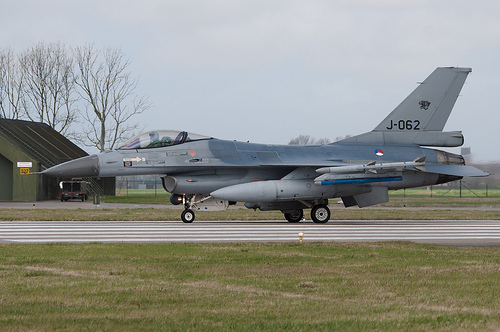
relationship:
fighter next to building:
[28, 66, 491, 221] [7, 130, 43, 198]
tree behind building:
[3, 62, 25, 113] [7, 130, 43, 198]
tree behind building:
[37, 66, 68, 122] [7, 130, 43, 198]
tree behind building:
[85, 84, 110, 139] [7, 130, 43, 198]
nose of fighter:
[35, 161, 97, 174] [28, 66, 491, 221]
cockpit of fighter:
[126, 126, 197, 148] [28, 66, 491, 221]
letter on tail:
[389, 119, 395, 137] [375, 63, 452, 142]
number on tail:
[401, 120, 423, 132] [375, 63, 452, 142]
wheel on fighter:
[312, 209, 335, 228] [28, 66, 491, 221]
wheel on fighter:
[179, 209, 199, 224] [28, 66, 491, 221]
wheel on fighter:
[290, 210, 302, 220] [28, 66, 491, 221]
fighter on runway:
[28, 66, 491, 221] [48, 225, 496, 238]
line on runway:
[62, 227, 71, 229] [48, 225, 496, 238]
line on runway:
[124, 232, 139, 237] [48, 225, 496, 238]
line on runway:
[163, 228, 169, 229] [48, 225, 496, 238]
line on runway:
[104, 219, 108, 222] [48, 225, 496, 238]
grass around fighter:
[51, 211, 173, 219] [28, 66, 491, 221]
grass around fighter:
[383, 209, 493, 221] [28, 66, 491, 221]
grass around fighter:
[23, 252, 499, 314] [28, 66, 491, 221]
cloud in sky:
[355, 27, 433, 56] [146, 9, 443, 64]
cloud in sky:
[94, 11, 153, 33] [146, 9, 443, 64]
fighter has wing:
[28, 66, 491, 221] [433, 163, 488, 176]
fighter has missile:
[28, 66, 491, 221] [326, 166, 417, 170]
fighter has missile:
[28, 66, 491, 221] [236, 185, 321, 198]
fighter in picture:
[28, 66, 491, 221] [1, 0, 498, 327]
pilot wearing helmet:
[145, 126, 159, 145] [147, 129, 156, 142]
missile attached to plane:
[315, 161, 435, 172] [36, 43, 490, 254]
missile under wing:
[207, 179, 380, 202] [159, 148, 474, 190]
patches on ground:
[3, 240, 494, 325] [35, 256, 497, 301]